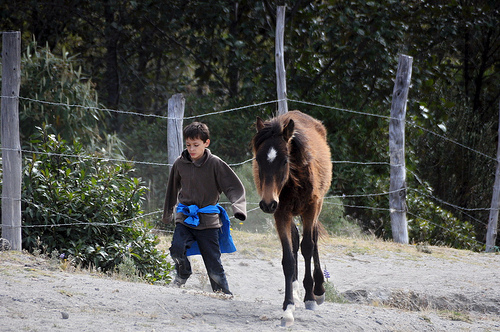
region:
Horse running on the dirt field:
[249, 110, 334, 328]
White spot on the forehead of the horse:
[266, 144, 277, 165]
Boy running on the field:
[160, 120, 248, 292]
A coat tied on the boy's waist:
[172, 202, 235, 256]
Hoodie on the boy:
[160, 148, 245, 230]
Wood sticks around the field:
[0, 6, 498, 250]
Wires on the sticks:
[1, 97, 497, 249]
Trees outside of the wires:
[5, 2, 497, 278]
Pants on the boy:
[168, 223, 228, 291]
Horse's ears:
[252, 112, 295, 143]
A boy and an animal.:
[155, 96, 350, 326]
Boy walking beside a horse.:
[167, 104, 338, 321]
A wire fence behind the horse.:
[5, 25, 497, 266]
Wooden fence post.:
[386, 46, 411, 244]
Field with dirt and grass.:
[4, 235, 499, 330]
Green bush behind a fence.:
[5, 28, 172, 288]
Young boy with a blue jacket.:
[157, 118, 250, 313]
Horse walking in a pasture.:
[251, 102, 331, 327]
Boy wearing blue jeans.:
[157, 114, 251, 301]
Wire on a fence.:
[286, 93, 395, 127]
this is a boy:
[158, 122, 238, 294]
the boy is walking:
[146, 123, 246, 299]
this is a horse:
[251, 110, 336, 300]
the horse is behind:
[234, 101, 337, 273]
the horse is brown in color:
[298, 134, 328, 184]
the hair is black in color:
[197, 125, 210, 136]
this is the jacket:
[185, 163, 232, 195]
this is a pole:
[377, 49, 419, 231]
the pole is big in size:
[378, 46, 423, 241]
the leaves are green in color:
[58, 163, 90, 199]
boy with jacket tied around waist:
[162, 190, 247, 262]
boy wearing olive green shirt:
[154, 140, 249, 232]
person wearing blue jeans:
[160, 208, 239, 293]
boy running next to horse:
[143, 97, 357, 320]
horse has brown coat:
[229, 88, 363, 322]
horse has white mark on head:
[260, 135, 282, 174]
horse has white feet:
[258, 281, 343, 326]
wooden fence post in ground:
[364, 38, 444, 265]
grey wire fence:
[20, 85, 480, 273]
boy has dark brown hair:
[171, 118, 216, 150]